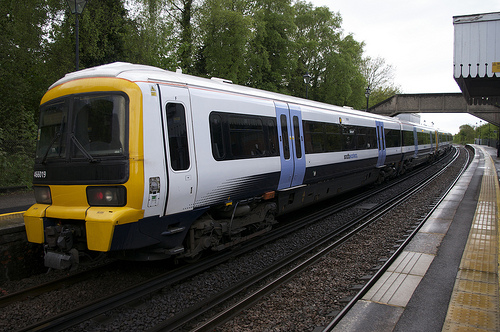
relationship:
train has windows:
[45, 46, 434, 258] [202, 117, 283, 160]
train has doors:
[45, 46, 434, 258] [270, 97, 310, 182]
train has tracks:
[45, 46, 434, 258] [10, 266, 120, 321]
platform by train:
[404, 210, 495, 325] [45, 46, 434, 258]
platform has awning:
[404, 210, 495, 325] [450, 15, 499, 83]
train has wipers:
[45, 46, 434, 258] [33, 124, 89, 174]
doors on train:
[270, 97, 310, 182] [45, 46, 434, 258]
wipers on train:
[33, 124, 89, 174] [45, 46, 434, 258]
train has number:
[45, 46, 434, 258] [26, 167, 53, 183]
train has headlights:
[45, 46, 434, 258] [24, 186, 138, 221]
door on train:
[141, 77, 210, 209] [45, 46, 434, 258]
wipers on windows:
[33, 124, 89, 174] [202, 117, 283, 160]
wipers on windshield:
[33, 124, 89, 174] [26, 98, 138, 174]